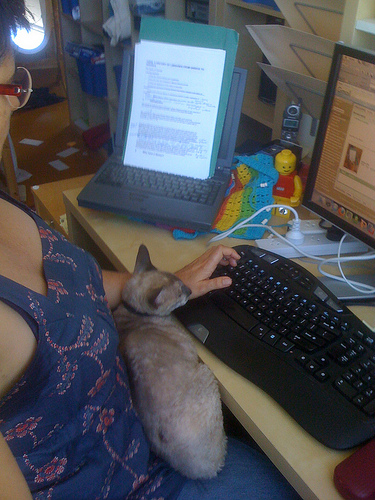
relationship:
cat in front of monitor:
[112, 241, 228, 480] [298, 41, 374, 250]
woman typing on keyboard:
[1, 0, 302, 497] [173, 244, 374, 451]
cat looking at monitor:
[112, 241, 228, 480] [298, 41, 374, 250]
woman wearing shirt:
[1, 0, 302, 497] [0, 190, 189, 498]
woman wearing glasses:
[1, 0, 302, 497] [0, 64, 34, 110]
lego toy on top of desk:
[266, 148, 301, 219] [62, 155, 372, 498]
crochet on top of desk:
[171, 149, 279, 242] [62, 155, 372, 498]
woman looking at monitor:
[1, 0, 302, 497] [298, 41, 374, 250]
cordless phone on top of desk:
[279, 96, 304, 147] [62, 155, 372, 498]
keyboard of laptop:
[94, 161, 221, 209] [77, 45, 247, 234]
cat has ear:
[112, 241, 228, 480] [131, 242, 157, 276]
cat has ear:
[112, 241, 228, 480] [146, 284, 168, 311]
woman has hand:
[1, 0, 302, 497] [172, 243, 242, 299]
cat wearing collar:
[112, 241, 228, 480] [118, 298, 149, 319]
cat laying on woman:
[112, 241, 228, 480] [1, 0, 302, 497]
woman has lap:
[1, 0, 302, 497] [148, 420, 287, 499]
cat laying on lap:
[112, 241, 228, 480] [148, 420, 287, 499]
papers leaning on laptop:
[122, 37, 227, 180] [77, 45, 247, 234]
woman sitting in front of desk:
[1, 0, 302, 497] [62, 155, 372, 498]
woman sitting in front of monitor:
[1, 0, 302, 497] [298, 41, 374, 250]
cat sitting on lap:
[112, 241, 228, 480] [148, 420, 287, 499]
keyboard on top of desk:
[173, 244, 374, 451] [62, 155, 372, 498]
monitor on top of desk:
[298, 41, 374, 250] [62, 155, 372, 498]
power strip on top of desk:
[253, 233, 369, 258] [62, 155, 372, 498]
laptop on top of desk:
[77, 45, 247, 234] [62, 155, 372, 498]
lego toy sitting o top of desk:
[266, 148, 301, 219] [62, 155, 372, 498]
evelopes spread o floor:
[18, 135, 79, 173] [7, 82, 109, 211]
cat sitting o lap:
[112, 241, 228, 480] [148, 420, 287, 499]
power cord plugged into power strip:
[206, 203, 374, 295] [253, 233, 369, 258]